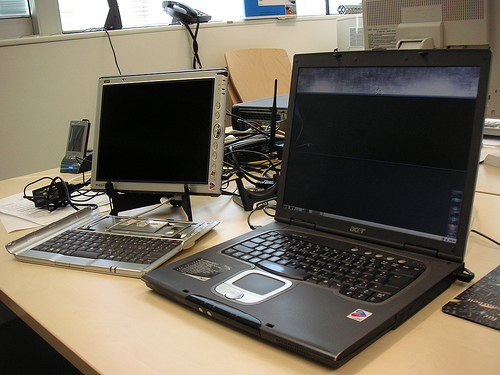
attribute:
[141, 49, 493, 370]
laptop — black, open, acer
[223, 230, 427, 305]
keyboard — black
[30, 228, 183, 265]
keyboard — black, detached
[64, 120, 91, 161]
cellphone — small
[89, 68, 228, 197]
monitor — silver, off, detached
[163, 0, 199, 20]
handset — black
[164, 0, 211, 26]
telephone — black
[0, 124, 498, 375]
desk — beige, wooden, wood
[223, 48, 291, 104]
chair back — wood, brown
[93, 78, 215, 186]
screen — black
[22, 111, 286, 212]
cords — messy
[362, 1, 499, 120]
monitor — gray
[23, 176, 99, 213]
power cord — wadded